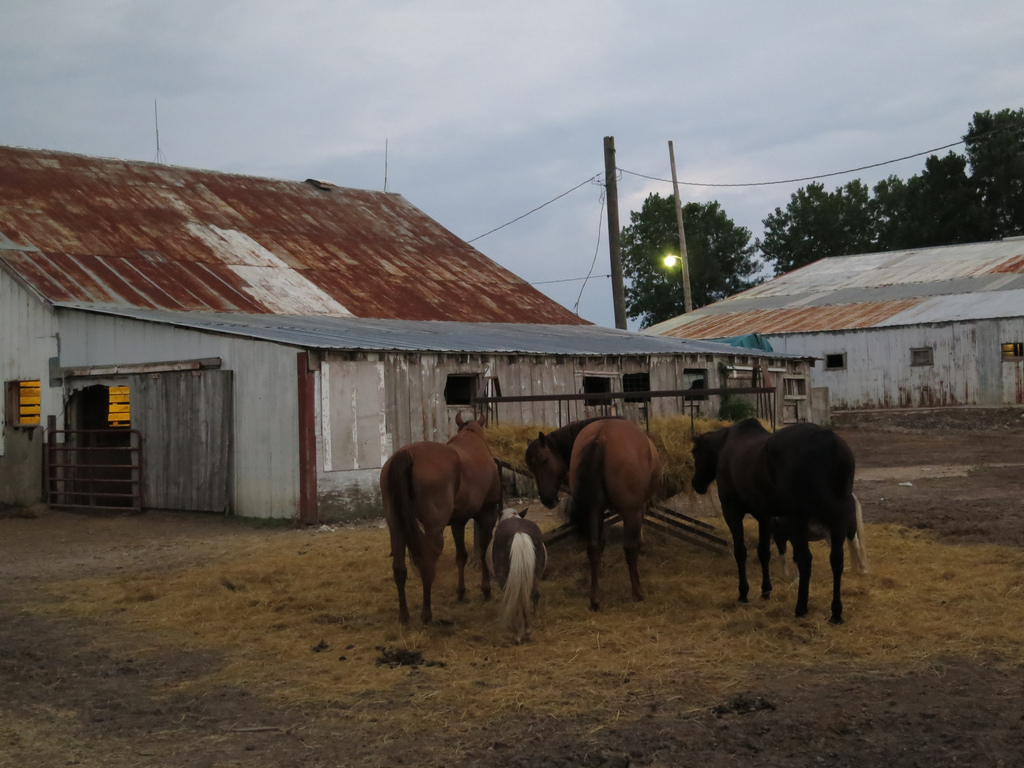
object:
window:
[583, 376, 611, 406]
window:
[622, 373, 649, 403]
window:
[684, 367, 709, 400]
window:
[827, 354, 843, 368]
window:
[909, 347, 933, 367]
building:
[640, 240, 1023, 410]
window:
[1002, 341, 1024, 362]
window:
[19, 380, 39, 424]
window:
[69, 385, 130, 510]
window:
[321, 362, 389, 473]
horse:
[692, 418, 857, 624]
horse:
[380, 411, 504, 624]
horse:
[526, 415, 661, 610]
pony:
[485, 508, 548, 636]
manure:
[373, 645, 425, 670]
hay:
[44, 523, 1024, 711]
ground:
[0, 408, 1022, 768]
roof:
[50, 301, 825, 362]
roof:
[0, 145, 595, 323]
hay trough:
[479, 414, 778, 556]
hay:
[482, 414, 784, 496]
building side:
[766, 319, 1021, 415]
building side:
[0, 261, 310, 520]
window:
[2, 367, 807, 514]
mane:
[539, 416, 627, 464]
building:
[0, 145, 829, 523]